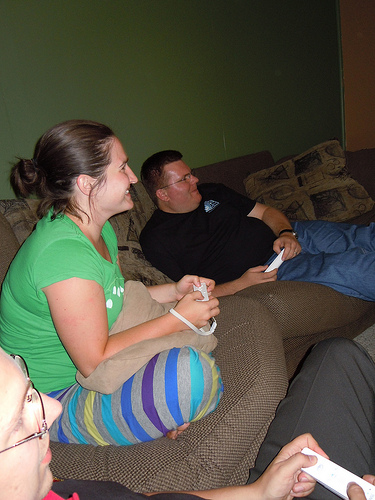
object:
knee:
[338, 255, 357, 282]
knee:
[175, 346, 206, 416]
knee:
[316, 338, 358, 353]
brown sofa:
[0, 141, 375, 491]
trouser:
[245, 333, 374, 499]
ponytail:
[8, 155, 40, 200]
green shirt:
[0, 205, 125, 395]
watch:
[278, 227, 299, 237]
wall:
[4, 3, 342, 175]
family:
[0, 117, 373, 500]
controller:
[256, 248, 299, 282]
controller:
[288, 439, 374, 496]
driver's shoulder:
[45, 233, 90, 279]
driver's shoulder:
[138, 213, 167, 254]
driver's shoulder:
[196, 176, 222, 193]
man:
[139, 146, 373, 325]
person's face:
[103, 135, 140, 211]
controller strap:
[169, 307, 220, 337]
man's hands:
[272, 233, 303, 262]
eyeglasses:
[161, 169, 196, 188]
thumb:
[278, 452, 319, 473]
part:
[283, 441, 302, 457]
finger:
[284, 433, 330, 461]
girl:
[0, 120, 224, 446]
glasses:
[1, 346, 49, 458]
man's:
[0, 338, 373, 497]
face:
[0, 349, 65, 499]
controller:
[193, 278, 210, 303]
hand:
[173, 290, 220, 331]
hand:
[174, 274, 215, 302]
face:
[160, 157, 202, 211]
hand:
[254, 430, 331, 498]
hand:
[344, 471, 375, 500]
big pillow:
[244, 139, 375, 224]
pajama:
[40, 346, 224, 447]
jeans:
[276, 221, 374, 301]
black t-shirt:
[139, 180, 276, 285]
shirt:
[1, 206, 133, 399]